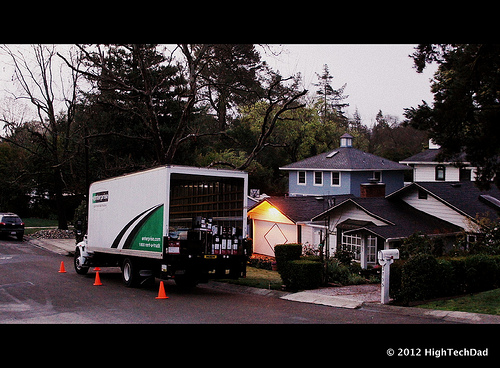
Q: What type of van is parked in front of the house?
A: Moving van.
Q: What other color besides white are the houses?
A: Blue.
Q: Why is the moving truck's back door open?
A: To load items in it.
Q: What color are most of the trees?
A: Brown and green.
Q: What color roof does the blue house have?
A: Gray.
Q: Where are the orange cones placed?
A: On street beside moving truck.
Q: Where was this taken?
A: Subdivision.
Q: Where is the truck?
A: Parked outside of the house.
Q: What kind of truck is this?
A: Moving truck.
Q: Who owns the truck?
A: Enterprise.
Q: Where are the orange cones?
A: Around the truck.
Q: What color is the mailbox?
A: White.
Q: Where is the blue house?
A: Behind the white house.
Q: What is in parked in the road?
A: A moving van.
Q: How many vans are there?
A: One.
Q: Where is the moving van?
A: By the sidewalk.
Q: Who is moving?
A: A family.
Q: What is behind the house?
A: Trees.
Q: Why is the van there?
A: To move furniture.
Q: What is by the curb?
A: A mailbox.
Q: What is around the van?
A: Cones.